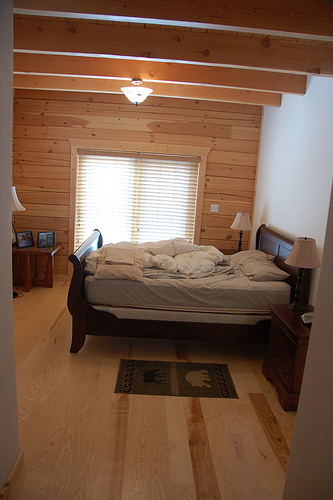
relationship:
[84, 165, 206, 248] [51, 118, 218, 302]
blinds on window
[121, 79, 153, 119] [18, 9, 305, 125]
light on ceiling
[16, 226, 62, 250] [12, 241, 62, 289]
picture on table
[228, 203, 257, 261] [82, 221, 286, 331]
lampshade beside bed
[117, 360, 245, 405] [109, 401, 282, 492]
rug on floor